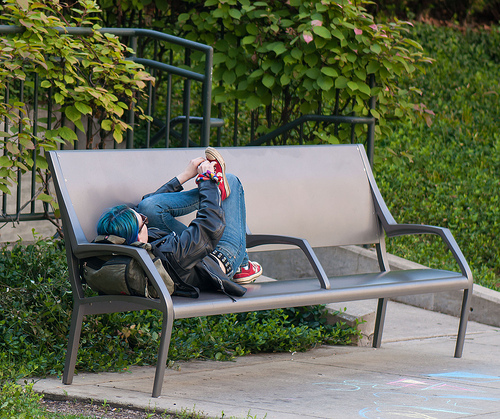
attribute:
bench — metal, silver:
[46, 139, 473, 398]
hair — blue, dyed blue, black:
[97, 204, 139, 246]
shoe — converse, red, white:
[201, 146, 230, 200]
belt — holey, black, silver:
[210, 247, 234, 276]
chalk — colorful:
[393, 356, 490, 407]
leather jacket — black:
[112, 175, 224, 298]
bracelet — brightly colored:
[194, 171, 214, 184]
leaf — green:
[302, 30, 315, 43]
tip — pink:
[305, 36, 312, 43]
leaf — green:
[352, 25, 363, 36]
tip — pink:
[355, 30, 365, 40]